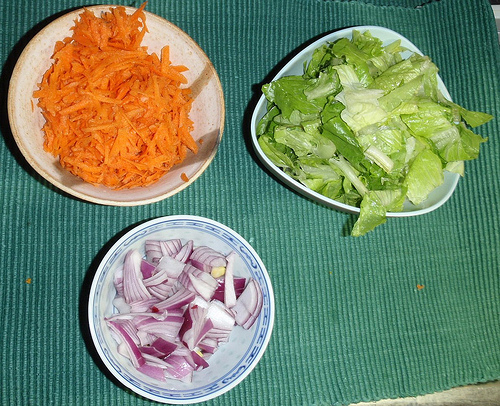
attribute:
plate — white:
[5, 6, 225, 206]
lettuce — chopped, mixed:
[226, 34, 457, 216]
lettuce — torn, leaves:
[286, 53, 441, 234]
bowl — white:
[216, 19, 489, 240]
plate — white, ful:
[240, 16, 472, 219]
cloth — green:
[1, 0, 495, 402]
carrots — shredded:
[32, 5, 198, 186]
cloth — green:
[311, 238, 476, 373]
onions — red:
[111, 250, 246, 367]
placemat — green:
[2, 1, 499, 404]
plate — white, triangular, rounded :
[245, 27, 462, 219]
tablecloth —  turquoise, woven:
[306, 256, 471, 353]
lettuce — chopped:
[254, 33, 486, 231]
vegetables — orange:
[69, 60, 154, 170]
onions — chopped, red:
[132, 255, 204, 365]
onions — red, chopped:
[127, 270, 210, 360]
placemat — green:
[290, 243, 497, 379]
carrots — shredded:
[56, 66, 179, 166]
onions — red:
[130, 259, 214, 368]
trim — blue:
[236, 338, 265, 371]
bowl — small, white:
[247, 23, 467, 217]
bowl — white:
[82, 212, 278, 403]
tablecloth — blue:
[2, 4, 479, 389]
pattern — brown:
[58, 64, 219, 183]